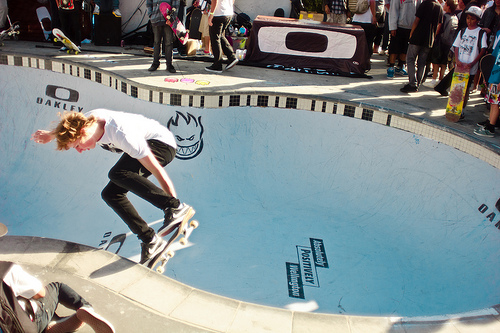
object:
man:
[31, 107, 194, 266]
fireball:
[164, 110, 205, 160]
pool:
[0, 54, 499, 316]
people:
[399, 1, 444, 95]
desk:
[243, 14, 369, 79]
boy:
[446, 5, 488, 121]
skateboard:
[445, 62, 471, 125]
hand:
[456, 60, 464, 68]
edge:
[1, 54, 499, 170]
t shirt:
[449, 25, 487, 75]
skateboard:
[140, 205, 200, 274]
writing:
[285, 236, 330, 300]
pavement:
[1, 38, 499, 151]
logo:
[36, 84, 84, 113]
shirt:
[80, 108, 178, 161]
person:
[206, 1, 240, 73]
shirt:
[209, 0, 233, 17]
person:
[352, 1, 377, 81]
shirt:
[351, 7, 374, 23]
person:
[388, 0, 417, 79]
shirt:
[388, 1, 418, 31]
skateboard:
[157, 3, 189, 46]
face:
[174, 133, 201, 157]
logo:
[99, 231, 113, 246]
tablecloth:
[246, 15, 369, 75]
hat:
[463, 6, 484, 20]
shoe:
[139, 236, 167, 262]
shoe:
[155, 202, 195, 237]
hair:
[52, 111, 96, 150]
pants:
[101, 140, 180, 244]